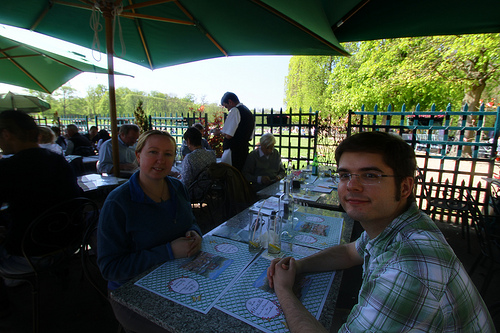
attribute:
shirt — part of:
[331, 199, 495, 331]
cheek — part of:
[392, 184, 406, 202]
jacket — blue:
[94, 167, 194, 292]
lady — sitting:
[90, 127, 207, 292]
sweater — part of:
[83, 173, 240, 306]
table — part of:
[154, 171, 366, 322]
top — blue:
[92, 175, 205, 279]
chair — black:
[18, 192, 106, 327]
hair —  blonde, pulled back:
[126, 126, 184, 148]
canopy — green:
[40, 0, 370, 65]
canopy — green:
[0, 46, 133, 83]